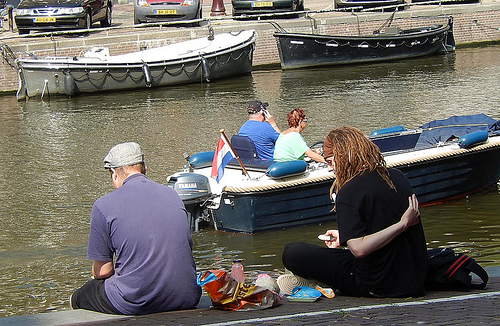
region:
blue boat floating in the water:
[149, 98, 499, 233]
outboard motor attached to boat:
[165, 173, 218, 231]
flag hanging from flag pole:
[205, 128, 252, 180]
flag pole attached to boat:
[219, 128, 254, 179]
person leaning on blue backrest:
[228, 134, 257, 159]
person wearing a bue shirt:
[238, 119, 278, 156]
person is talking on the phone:
[229, 98, 279, 157]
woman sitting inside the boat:
[271, 108, 328, 165]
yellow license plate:
[31, 15, 55, 25]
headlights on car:
[60, 7, 82, 13]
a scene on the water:
[27, 9, 499, 291]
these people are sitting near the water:
[79, 130, 474, 310]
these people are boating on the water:
[152, 81, 497, 183]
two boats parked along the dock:
[6, 7, 484, 98]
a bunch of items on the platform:
[185, 252, 324, 321]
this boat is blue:
[194, 94, 499, 216]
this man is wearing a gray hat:
[82, 139, 156, 189]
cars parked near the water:
[9, 1, 299, 26]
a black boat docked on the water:
[271, 14, 466, 82]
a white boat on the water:
[7, 25, 266, 109]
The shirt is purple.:
[87, 173, 203, 315]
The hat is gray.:
[101, 140, 146, 169]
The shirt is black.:
[335, 167, 432, 294]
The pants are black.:
[281, 240, 358, 291]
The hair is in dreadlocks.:
[324, 124, 399, 202]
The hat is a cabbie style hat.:
[101, 140, 146, 172]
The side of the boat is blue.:
[167, 112, 498, 229]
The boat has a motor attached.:
[166, 170, 216, 231]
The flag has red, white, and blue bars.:
[210, 128, 235, 183]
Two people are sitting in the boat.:
[234, 96, 331, 169]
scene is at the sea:
[44, 42, 489, 320]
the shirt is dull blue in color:
[86, 209, 192, 286]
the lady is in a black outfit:
[322, 177, 437, 275]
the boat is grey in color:
[28, 42, 280, 84]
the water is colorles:
[94, 82, 231, 131]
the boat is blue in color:
[225, 189, 340, 223]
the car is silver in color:
[142, 0, 201, 20]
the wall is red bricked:
[458, 10, 497, 35]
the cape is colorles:
[89, 132, 162, 172]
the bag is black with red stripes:
[421, 247, 498, 300]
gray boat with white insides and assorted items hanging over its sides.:
[14, 31, 255, 98]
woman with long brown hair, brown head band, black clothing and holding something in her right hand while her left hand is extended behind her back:
[281, 125, 433, 299]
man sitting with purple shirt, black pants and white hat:
[69, 140, 201, 312]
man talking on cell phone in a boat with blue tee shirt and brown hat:
[237, 101, 282, 161]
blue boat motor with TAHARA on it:
[161, 174, 219, 231]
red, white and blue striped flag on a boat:
[210, 129, 247, 184]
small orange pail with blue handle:
[195, 267, 228, 303]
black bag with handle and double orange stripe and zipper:
[426, 244, 489, 289]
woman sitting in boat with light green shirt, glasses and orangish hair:
[273, 109, 328, 167]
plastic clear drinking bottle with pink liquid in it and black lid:
[230, 258, 244, 283]